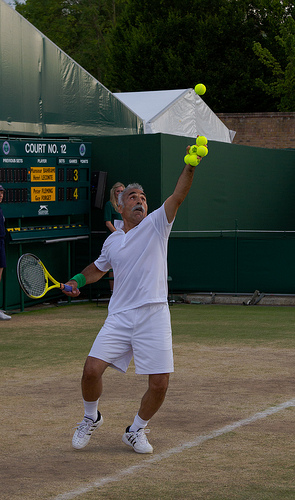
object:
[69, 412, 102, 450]
shoe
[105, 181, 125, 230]
person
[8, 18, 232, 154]
tents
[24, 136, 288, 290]
walls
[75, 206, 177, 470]
white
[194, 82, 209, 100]
tennis ball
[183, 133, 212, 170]
five tennis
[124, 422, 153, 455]
shoe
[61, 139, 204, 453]
man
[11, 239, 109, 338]
racket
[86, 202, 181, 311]
t-shirt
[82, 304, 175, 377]
shorts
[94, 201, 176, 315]
shirt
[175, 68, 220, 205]
tennis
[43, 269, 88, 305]
hand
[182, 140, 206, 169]
hand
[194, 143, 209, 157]
tennis ball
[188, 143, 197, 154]
tennis ball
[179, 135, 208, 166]
held balls